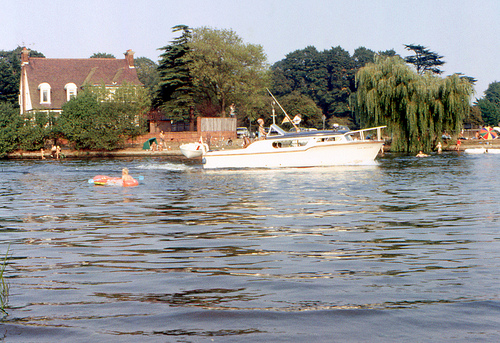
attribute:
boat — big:
[195, 116, 389, 176]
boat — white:
[202, 122, 386, 167]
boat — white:
[203, 117, 385, 172]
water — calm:
[0, 147, 498, 342]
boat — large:
[200, 87, 386, 177]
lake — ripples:
[241, 194, 431, 291]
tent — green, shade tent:
[138, 131, 160, 154]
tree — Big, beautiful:
[356, 56, 475, 163]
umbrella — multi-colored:
[476, 122, 498, 145]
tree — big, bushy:
[138, 17, 265, 157]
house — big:
[15, 47, 147, 129]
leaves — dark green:
[310, 64, 334, 97]